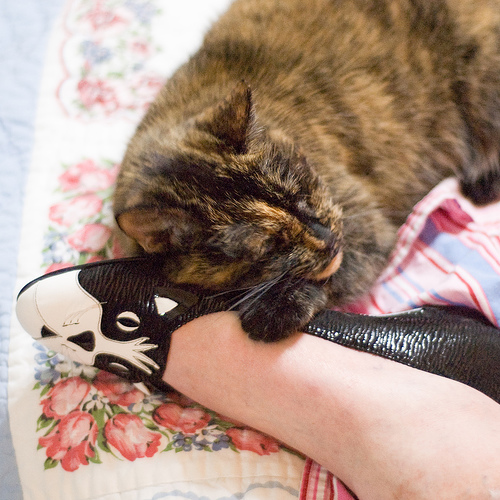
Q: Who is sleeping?
A: The cat.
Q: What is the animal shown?
A: Cat.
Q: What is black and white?
A: Woman's shoe.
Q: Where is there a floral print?
A: Blanket under foot.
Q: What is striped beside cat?
A: Sheet.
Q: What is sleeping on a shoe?
A: Cat.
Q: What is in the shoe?
A: Foot.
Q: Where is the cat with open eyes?
A: Tip of shoe.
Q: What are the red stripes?
A: Sheet.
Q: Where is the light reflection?
A: Side of shoe.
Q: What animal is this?
A: Cat.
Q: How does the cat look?
A: Content.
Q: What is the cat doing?
A: Sleeping.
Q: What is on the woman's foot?
A: Cat shaped shoe.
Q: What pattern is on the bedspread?
A: Floral.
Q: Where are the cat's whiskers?
A: On its face.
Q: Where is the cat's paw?
A: On the foot.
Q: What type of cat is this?
A: Calico.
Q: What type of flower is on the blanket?
A: Roses.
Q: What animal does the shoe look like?
A: A cat.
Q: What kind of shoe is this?
A: Flat.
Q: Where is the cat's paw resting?
A: On the shoe.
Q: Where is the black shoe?
A: On the person's foot.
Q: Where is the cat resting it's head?
A: On persons foot.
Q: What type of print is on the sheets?
A: Floral.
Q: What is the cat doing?
A: Resting.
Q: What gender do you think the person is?
A: Female.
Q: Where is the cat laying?
A: On the bed.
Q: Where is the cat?
A: On the bed.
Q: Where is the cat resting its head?
A: On the shoe.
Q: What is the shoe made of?
A: Leather.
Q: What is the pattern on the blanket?
A: A flower pattern.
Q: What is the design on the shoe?
A: A cat's face.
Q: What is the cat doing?
A: Sleeping.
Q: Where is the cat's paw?
A: On the woman's foot.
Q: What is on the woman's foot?
A: A shoe.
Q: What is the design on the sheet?
A: Pink, blue and red stripes.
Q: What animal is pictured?
A: Cat.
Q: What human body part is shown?
A: Foot.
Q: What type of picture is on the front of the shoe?
A: Cat.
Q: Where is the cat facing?
A: Right.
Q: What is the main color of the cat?
A: Brown.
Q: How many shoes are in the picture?
A: One.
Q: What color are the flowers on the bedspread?
A: Pink.